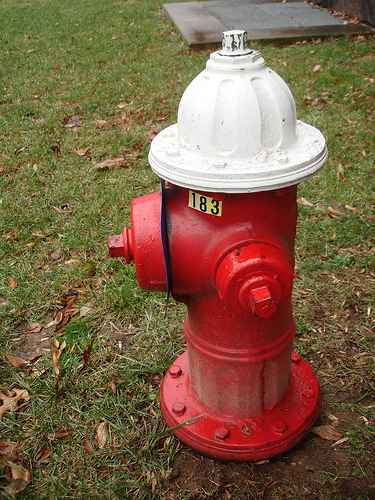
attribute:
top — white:
[147, 28, 327, 194]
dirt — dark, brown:
[152, 390, 373, 498]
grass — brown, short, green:
[0, 0, 160, 196]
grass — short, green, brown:
[3, 6, 109, 406]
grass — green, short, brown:
[55, 98, 138, 173]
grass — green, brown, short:
[13, 16, 354, 485]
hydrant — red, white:
[104, 26, 341, 463]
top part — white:
[151, 30, 339, 200]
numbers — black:
[184, 189, 222, 218]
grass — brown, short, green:
[19, 33, 70, 61]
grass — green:
[4, 3, 148, 183]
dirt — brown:
[174, 455, 212, 488]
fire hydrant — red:
[106, 29, 327, 459]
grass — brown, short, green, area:
[0, 1, 374, 499]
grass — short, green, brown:
[2, 2, 158, 499]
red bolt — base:
[214, 425, 229, 438]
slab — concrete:
[162, 0, 355, 51]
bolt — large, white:
[221, 28, 247, 55]